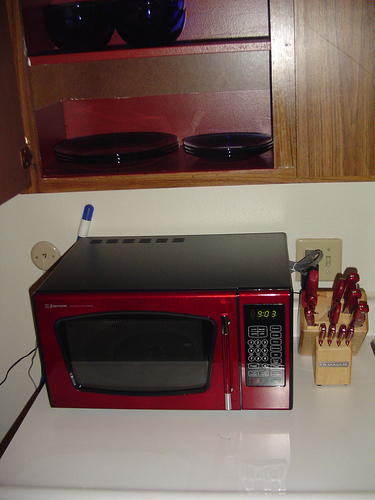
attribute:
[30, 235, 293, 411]
microwave — red, black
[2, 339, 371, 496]
counter — white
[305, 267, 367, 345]
knives — red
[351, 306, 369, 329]
handle of knife — red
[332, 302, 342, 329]
handle of knife — red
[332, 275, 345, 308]
handle of knife — red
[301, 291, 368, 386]
knife holder — wooden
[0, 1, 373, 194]
cabinet — brown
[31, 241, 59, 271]
telephone outlet — tan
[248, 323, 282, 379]
control panel — digital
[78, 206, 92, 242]
handle — blue, white